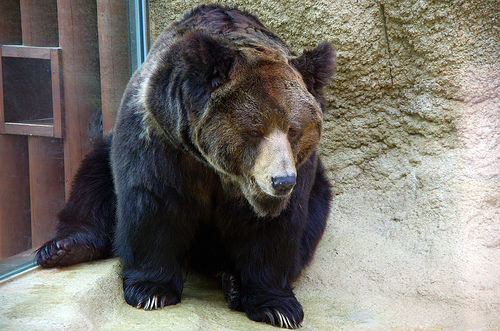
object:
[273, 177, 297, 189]
nose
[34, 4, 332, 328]
bear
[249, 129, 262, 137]
eye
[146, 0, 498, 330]
rock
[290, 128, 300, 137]
eye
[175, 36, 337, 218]
head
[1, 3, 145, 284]
wall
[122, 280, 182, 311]
claws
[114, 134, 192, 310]
leg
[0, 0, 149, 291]
racks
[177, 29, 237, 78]
ear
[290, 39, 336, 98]
ear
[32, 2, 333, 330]
hair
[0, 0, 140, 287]
glass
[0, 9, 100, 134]
structure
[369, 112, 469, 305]
stone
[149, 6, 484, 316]
wall